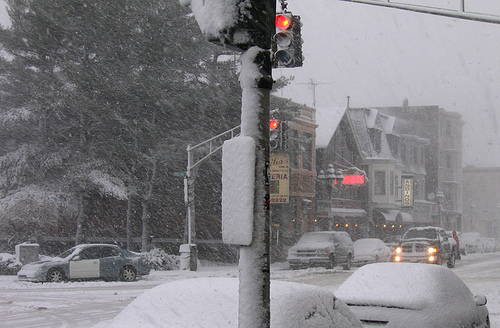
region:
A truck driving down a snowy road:
[392, 222, 463, 265]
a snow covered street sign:
[222, 138, 255, 248]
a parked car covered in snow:
[342, 258, 490, 323]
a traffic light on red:
[274, 11, 303, 68]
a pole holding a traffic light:
[184, 146, 200, 268]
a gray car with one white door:
[21, 243, 153, 280]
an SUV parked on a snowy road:
[289, 231, 353, 270]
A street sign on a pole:
[172, 167, 189, 177]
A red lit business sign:
[342, 173, 367, 183]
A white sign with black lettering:
[272, 170, 289, 202]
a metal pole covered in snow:
[188, 4, 284, 326]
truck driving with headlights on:
[390, 223, 453, 264]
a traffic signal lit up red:
[273, 9, 301, 71]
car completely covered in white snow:
[343, 260, 486, 325]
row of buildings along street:
[145, 110, 464, 268]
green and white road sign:
[173, 169, 193, 177]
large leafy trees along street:
[0, 1, 236, 263]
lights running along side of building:
[329, 218, 406, 231]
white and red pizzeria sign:
[269, 155, 289, 203]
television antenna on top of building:
[298, 74, 328, 108]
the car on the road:
[17, 242, 149, 282]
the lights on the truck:
[392, 246, 435, 263]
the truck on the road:
[394, 225, 458, 268]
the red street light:
[275, 13, 290, 29]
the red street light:
[268, 119, 278, 131]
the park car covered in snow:
[91, 276, 367, 326]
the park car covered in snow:
[333, 262, 489, 327]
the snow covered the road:
[0, 246, 497, 326]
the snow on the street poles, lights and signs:
[172, 0, 303, 327]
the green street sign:
[170, 170, 185, 177]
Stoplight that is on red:
[272, 11, 300, 66]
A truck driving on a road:
[396, 223, 459, 263]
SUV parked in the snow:
[287, 228, 354, 269]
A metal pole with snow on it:
[182, 1, 269, 326]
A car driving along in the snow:
[16, 245, 151, 282]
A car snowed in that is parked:
[333, 259, 488, 326]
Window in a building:
[375, 169, 386, 194]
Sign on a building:
[267, 151, 288, 203]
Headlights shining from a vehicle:
[395, 245, 404, 260]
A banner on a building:
[400, 173, 413, 207]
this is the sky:
[330, 17, 483, 74]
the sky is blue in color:
[371, 24, 422, 119]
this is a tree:
[81, 13, 163, 136]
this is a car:
[296, 225, 343, 266]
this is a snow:
[374, 267, 439, 304]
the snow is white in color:
[354, 266, 415, 289]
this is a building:
[361, 101, 443, 220]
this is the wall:
[290, 165, 315, 195]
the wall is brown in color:
[291, 166, 308, 191]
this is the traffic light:
[278, 12, 300, 54]